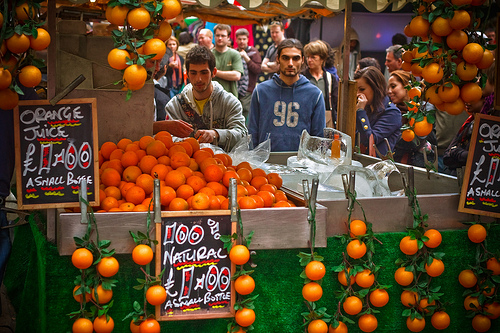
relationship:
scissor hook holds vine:
[298, 172, 326, 220] [306, 221, 318, 256]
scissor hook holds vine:
[337, 164, 359, 209] [341, 202, 354, 227]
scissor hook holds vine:
[399, 159, 421, 206] [408, 194, 425, 223]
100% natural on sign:
[163, 220, 226, 265] [138, 197, 244, 324]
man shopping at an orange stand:
[163, 44, 250, 152] [34, 127, 498, 332]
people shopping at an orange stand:
[245, 37, 328, 154] [34, 127, 498, 332]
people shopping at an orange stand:
[354, 64, 404, 157] [34, 127, 498, 332]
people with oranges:
[257, 37, 332, 154] [110, 132, 260, 215]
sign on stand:
[146, 206, 241, 317] [54, 203, 328, 254]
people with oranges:
[356, 66, 403, 161] [257, 190, 275, 205]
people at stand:
[150, 20, 417, 164] [1, 1, 488, 320]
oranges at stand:
[73, 221, 498, 329] [18, 155, 495, 329]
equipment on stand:
[268, 129, 402, 201] [0, 147, 499, 245]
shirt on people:
[245, 71, 328, 153] [245, 37, 328, 154]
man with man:
[175, 54, 256, 131] [163, 44, 250, 152]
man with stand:
[175, 54, 256, 131] [106, 71, 188, 163]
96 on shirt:
[271, 98, 301, 128] [244, 39, 326, 151]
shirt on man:
[252, 74, 327, 149] [256, 44, 324, 166]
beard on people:
[281, 67, 301, 79] [245, 37, 328, 154]